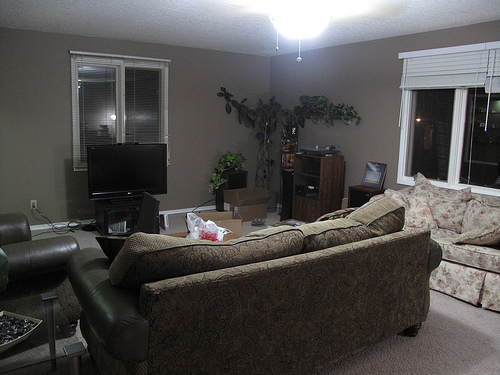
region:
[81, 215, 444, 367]
A floral patterned sofa with leather arms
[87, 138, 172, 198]
A flat screen TV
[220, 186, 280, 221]
An opened cardboard box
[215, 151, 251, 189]
A plant on top of a speaker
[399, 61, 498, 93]
White window blinds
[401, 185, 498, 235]
Floral patterned throw pillows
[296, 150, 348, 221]
An entertainment center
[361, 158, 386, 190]
a picture on top of a speaker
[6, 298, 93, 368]
A clear glass topped end table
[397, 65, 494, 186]
A window with the blinds drawn up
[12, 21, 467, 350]
A living room setting.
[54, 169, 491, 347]
Two sofas in a living room.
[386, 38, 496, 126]
White blinds on a window.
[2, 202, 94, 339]
Brown chair next to a brown sofa.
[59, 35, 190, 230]
Television placed in front of a window.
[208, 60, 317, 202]
Plant in the corner.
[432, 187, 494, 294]
Tan sofa in a living room.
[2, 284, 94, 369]
Glass table next to the sofa.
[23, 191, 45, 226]
One outlet on a brown wall.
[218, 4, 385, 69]
Ceiling light turned on.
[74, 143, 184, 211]
the screen is black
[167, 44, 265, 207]
the wall is gray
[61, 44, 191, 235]
window pane is white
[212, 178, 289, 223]
the box is open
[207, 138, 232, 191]
the leaves are green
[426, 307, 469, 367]
the floor is carpeted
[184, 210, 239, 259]
the plastic is white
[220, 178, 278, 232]
the box is brown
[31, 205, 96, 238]
the cord is black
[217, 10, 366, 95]
the light is on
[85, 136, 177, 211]
the television is black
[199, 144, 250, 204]
the plant is green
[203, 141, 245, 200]
the plant is a vine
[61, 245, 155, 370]
the couch has leather arms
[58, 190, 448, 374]
the couch has a brown pattern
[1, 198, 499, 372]
the carpet is light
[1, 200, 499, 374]
the carpet is beige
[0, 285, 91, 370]
the table is glass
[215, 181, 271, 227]
the box is cardboard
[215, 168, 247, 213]
the speaker is against the wall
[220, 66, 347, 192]
large indoor plant in corner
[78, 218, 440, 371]
two cushions on sofa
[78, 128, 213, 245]
black tv on black stand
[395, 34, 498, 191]
white framed window with white blinds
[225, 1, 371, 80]
bright ceiling lamp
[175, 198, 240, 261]
white and red plastic bag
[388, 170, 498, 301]
flower patterned sofa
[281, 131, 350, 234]
brown stand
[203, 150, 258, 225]
small green indoor plant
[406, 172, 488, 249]
flowery tan sofa cushions